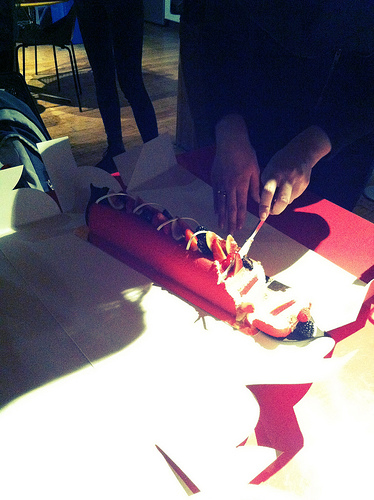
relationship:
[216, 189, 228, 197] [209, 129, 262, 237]
ring on hand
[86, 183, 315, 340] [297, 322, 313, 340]
cake has fruit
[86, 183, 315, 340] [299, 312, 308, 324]
cake has fruit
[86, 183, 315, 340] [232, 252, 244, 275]
cake has fruit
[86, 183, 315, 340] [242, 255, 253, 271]
cake has fruit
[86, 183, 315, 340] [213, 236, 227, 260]
cake has fruit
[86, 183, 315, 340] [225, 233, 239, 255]
cake has fruit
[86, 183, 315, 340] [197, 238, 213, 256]
cake has fruit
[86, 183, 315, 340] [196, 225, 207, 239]
cake has fruit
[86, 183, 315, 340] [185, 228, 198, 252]
cake has fruit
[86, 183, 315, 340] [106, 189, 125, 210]
cake has fruit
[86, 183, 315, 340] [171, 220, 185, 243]
cake has fruit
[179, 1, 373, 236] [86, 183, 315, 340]
person cutting cake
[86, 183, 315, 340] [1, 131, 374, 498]
cake on box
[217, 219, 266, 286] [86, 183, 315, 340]
knife cutting cake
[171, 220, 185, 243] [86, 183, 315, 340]
fruit on cake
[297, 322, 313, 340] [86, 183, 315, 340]
fruit on cake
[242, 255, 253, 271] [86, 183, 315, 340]
fruit on cake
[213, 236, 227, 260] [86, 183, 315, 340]
fruit on cake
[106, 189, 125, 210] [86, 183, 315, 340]
fruit on cake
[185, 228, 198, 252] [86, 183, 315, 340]
fruit on cake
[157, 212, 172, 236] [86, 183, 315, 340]
fruit on cake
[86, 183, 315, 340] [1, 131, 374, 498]
cake in box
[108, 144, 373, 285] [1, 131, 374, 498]
table under box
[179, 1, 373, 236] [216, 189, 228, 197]
person wearing ring